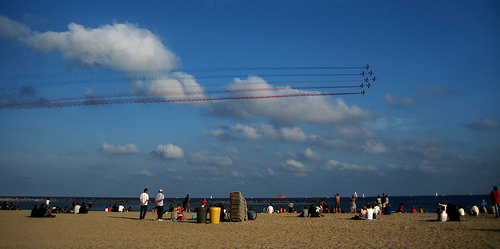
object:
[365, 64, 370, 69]
jet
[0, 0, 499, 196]
sky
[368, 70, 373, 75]
jet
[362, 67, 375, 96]
jet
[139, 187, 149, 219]
person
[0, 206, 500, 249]
beach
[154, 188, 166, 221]
person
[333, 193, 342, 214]
person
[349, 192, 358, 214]
person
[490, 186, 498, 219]
person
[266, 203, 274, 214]
person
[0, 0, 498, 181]
cloud